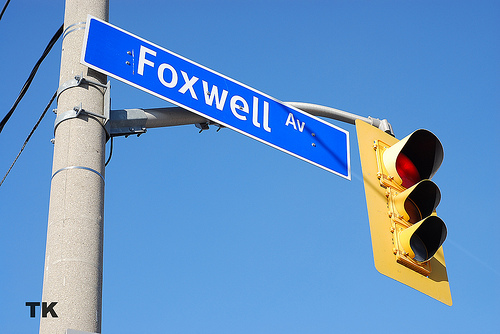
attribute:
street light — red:
[366, 114, 448, 285]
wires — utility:
[1, 46, 63, 138]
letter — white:
[129, 39, 159, 93]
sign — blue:
[60, 20, 352, 172]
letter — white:
[133, 42, 158, 77]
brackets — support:
[51, 70, 109, 100]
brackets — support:
[45, 102, 107, 132]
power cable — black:
[0, 87, 60, 192]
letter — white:
[124, 53, 266, 140]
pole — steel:
[45, 108, 115, 287]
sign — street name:
[119, 37, 348, 173]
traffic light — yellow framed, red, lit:
[355, 119, 451, 305]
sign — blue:
[91, 19, 325, 191]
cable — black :
[1, 21, 63, 131]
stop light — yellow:
[356, 116, 452, 306]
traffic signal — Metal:
[342, 105, 467, 316]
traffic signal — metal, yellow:
[302, 85, 499, 320]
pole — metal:
[40, 3, 108, 333]